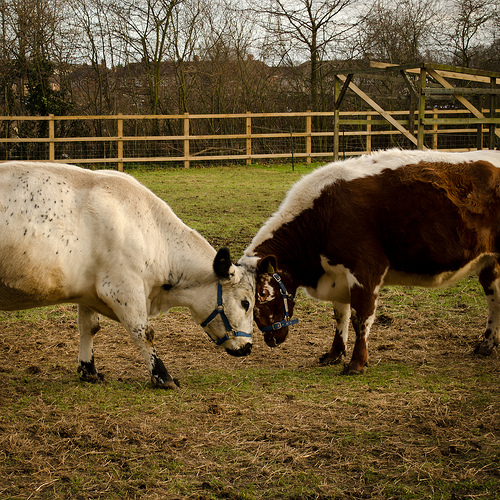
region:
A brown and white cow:
[245, 147, 495, 389]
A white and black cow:
[2, 166, 297, 404]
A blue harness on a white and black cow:
[184, 251, 254, 354]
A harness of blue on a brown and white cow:
[246, 253, 308, 338]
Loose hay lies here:
[261, 390, 393, 468]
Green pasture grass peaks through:
[200, 373, 322, 388]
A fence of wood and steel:
[0, 107, 495, 158]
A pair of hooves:
[66, 340, 188, 401]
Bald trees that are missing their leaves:
[77, 3, 155, 106]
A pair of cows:
[20, 142, 472, 384]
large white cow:
[1, 161, 254, 388]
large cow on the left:
[1, 161, 254, 388]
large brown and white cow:
[238, 148, 497, 367]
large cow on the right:
[240, 148, 498, 375]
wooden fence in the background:
[0, 110, 499, 163]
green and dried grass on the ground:
[0, 163, 497, 498]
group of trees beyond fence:
[5, 1, 498, 160]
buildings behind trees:
[6, 55, 454, 105]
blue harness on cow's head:
[201, 278, 254, 348]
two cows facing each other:
[1, 148, 497, 386]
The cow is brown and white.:
[245, 134, 497, 358]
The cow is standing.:
[246, 134, 496, 364]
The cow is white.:
[6, 155, 261, 396]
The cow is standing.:
[2, 143, 259, 405]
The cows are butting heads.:
[2, 151, 498, 386]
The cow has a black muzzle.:
[187, 249, 255, 364]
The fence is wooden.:
[8, 107, 497, 168]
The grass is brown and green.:
[15, 346, 495, 497]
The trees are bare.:
[5, 3, 497, 95]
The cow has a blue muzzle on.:
[243, 240, 313, 336]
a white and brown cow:
[244, 147, 499, 357]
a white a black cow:
[0, 163, 254, 395]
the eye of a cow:
[237, 295, 252, 312]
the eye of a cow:
[259, 288, 269, 300]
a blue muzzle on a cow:
[201, 286, 254, 349]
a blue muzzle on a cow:
[252, 270, 298, 332]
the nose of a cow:
[230, 338, 254, 356]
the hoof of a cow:
[146, 370, 181, 389]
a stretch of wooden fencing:
[0, 109, 497, 164]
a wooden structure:
[330, 53, 498, 156]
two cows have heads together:
[5, 155, 490, 382]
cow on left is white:
[1, 148, 237, 381]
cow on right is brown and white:
[292, 122, 477, 379]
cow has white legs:
[115, 261, 167, 356]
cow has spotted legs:
[303, 263, 375, 368]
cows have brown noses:
[238, 311, 286, 367]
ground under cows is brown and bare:
[145, 321, 353, 474]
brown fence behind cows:
[120, 71, 314, 168]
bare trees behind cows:
[98, 21, 223, 75]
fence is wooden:
[193, 98, 363, 180]